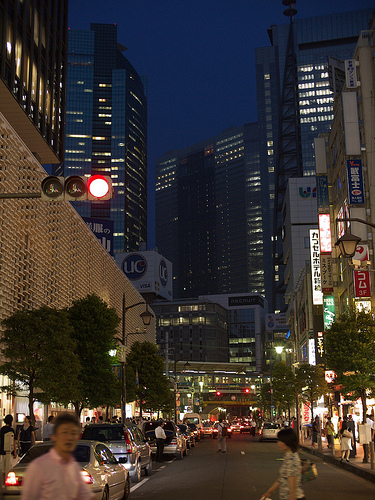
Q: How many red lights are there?
A: Three.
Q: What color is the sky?
A: Dark Blue.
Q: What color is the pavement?
A: Dark Gray.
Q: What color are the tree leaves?
A: Dark Green.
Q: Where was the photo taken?
A: In the city.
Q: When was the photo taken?
A: Night Time.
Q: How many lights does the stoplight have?
A: Three.